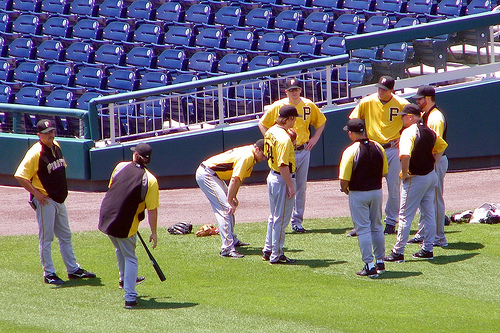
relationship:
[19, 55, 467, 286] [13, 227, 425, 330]
pirates on field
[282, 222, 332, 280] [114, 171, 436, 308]
shadows on ground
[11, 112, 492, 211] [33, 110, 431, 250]
men in group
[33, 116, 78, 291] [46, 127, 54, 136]
man with sunglasses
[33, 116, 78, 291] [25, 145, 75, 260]
man in attire